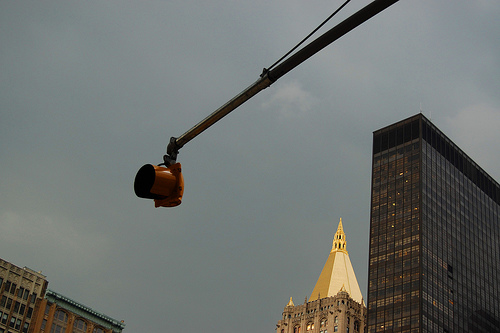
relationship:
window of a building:
[56, 311, 68, 322] [0, 259, 128, 333]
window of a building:
[4, 297, 15, 312] [0, 259, 128, 333]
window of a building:
[29, 291, 39, 306] [0, 259, 128, 333]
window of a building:
[22, 288, 32, 301] [0, 259, 128, 333]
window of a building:
[17, 284, 25, 299] [0, 259, 128, 333]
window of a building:
[9, 282, 18, 296] [0, 259, 128, 333]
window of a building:
[2, 279, 12, 294] [0, 259, 128, 333]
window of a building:
[13, 300, 21, 315] [0, 259, 128, 333]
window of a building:
[18, 302, 29, 316] [0, 259, 128, 333]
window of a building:
[26, 307, 35, 320] [0, 259, 128, 333]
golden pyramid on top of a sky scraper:
[305, 216, 366, 290] [273, 216, 366, 331]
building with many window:
[367, 113, 500, 332] [373, 208, 500, 304]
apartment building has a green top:
[0, 259, 128, 333] [46, 288, 127, 331]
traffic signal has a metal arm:
[133, 163, 186, 209] [162, 2, 399, 165]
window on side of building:
[2, 279, 12, 294] [0, 259, 128, 333]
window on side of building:
[9, 282, 18, 296] [0, 259, 128, 333]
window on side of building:
[17, 284, 25, 299] [0, 259, 128, 333]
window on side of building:
[22, 288, 32, 301] [0, 259, 128, 333]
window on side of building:
[29, 291, 39, 306] [0, 259, 128, 333]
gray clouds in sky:
[2, 146, 120, 256] [1, 1, 500, 111]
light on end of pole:
[132, 161, 186, 208] [162, 2, 399, 165]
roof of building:
[46, 288, 127, 331] [0, 259, 128, 333]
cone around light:
[133, 162, 186, 208] [132, 161, 186, 208]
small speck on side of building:
[447, 286, 457, 297] [367, 113, 500, 332]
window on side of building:
[4, 297, 15, 312] [0, 259, 128, 333]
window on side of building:
[13, 300, 21, 315] [0, 259, 128, 333]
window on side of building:
[18, 302, 29, 316] [0, 259, 128, 333]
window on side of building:
[26, 307, 35, 320] [0, 259, 128, 333]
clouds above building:
[272, 1, 498, 113] [367, 113, 500, 332]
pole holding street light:
[162, 2, 399, 165] [132, 161, 186, 208]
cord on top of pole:
[258, 0, 350, 72] [162, 2, 399, 165]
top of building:
[46, 288, 127, 331] [0, 259, 128, 333]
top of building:
[372, 111, 500, 185] [367, 113, 500, 332]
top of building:
[305, 216, 366, 290] [276, 288, 366, 332]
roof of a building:
[2, 254, 52, 285] [0, 259, 128, 333]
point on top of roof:
[336, 214, 345, 223] [329, 214, 349, 251]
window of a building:
[333, 315, 341, 324] [276, 288, 366, 332]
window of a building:
[333, 324, 341, 332] [276, 288, 366, 332]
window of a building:
[352, 319, 361, 330] [276, 288, 366, 332]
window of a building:
[285, 312, 294, 320] [276, 288, 366, 332]